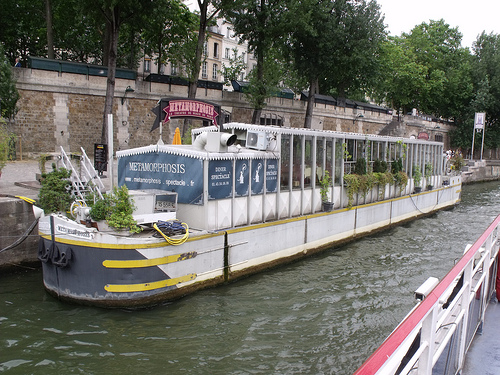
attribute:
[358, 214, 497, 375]
fence — red, white, painted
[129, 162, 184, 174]
word — white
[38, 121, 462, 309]
structure — white, long, passing, still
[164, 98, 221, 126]
sign — red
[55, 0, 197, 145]
tree — leafy, tall, green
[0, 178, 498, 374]
water — rippled, dark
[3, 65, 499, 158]
wall — brick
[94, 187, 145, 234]
vegetation — green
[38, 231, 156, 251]
strip — yellow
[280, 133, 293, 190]
window — glass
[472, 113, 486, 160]
sign — tall, white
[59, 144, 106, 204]
stairs — metal, white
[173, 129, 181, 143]
umbrella — yellow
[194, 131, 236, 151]
tube — metal